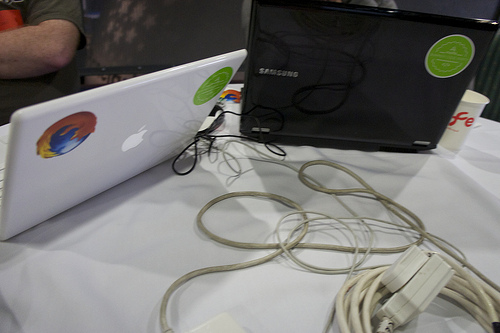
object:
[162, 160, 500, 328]
cord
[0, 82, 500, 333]
table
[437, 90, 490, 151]
coffee cup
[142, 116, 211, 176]
sticker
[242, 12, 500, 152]
computer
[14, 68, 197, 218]
laptop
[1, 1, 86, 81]
arm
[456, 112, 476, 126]
letters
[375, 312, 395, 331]
outlet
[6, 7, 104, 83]
man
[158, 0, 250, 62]
wall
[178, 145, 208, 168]
elbow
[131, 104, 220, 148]
t-shirt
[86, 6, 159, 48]
lights